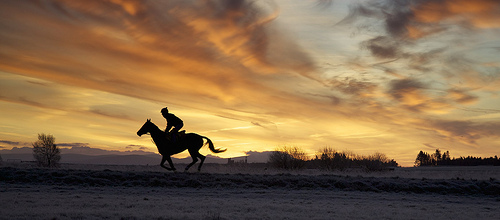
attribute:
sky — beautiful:
[4, 3, 497, 111]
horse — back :
[134, 110, 211, 177]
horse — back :
[118, 114, 243, 199]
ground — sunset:
[420, 113, 448, 138]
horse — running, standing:
[133, 118, 225, 170]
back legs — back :
[191, 148, 214, 177]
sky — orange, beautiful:
[1, 1, 498, 171]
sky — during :
[6, 5, 454, 107]